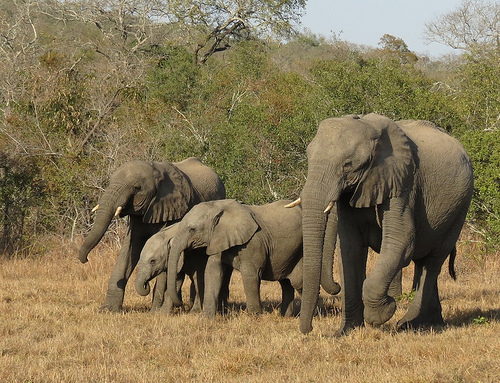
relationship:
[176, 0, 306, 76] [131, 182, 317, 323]
branches of a tree and her babies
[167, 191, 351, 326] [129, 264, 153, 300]
baby elephant curls its trunk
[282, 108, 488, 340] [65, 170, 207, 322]
big elephant has huge tusks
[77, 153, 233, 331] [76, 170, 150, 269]
grey elephant has its head raised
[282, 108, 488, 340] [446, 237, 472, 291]
big elephant has short tail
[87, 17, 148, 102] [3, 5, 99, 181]
dead branches near trees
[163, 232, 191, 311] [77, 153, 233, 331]
gray elephant trunk of an grey elephant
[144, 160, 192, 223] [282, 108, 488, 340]
an ear of an big elephant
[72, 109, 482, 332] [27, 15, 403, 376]
four elephants in savanna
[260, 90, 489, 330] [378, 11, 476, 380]
big elephant on right side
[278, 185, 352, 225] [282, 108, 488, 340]
two tusks of big elephant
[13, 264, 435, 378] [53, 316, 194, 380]
field covered with dry grass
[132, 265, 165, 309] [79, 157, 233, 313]
trunk is fold of elephant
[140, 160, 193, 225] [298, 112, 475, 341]
an ear of elephant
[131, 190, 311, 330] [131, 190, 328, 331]
elephant in middle of elephant in middle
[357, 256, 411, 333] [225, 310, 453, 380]
foot lifted off ground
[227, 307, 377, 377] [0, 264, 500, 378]
light brown grass covering field